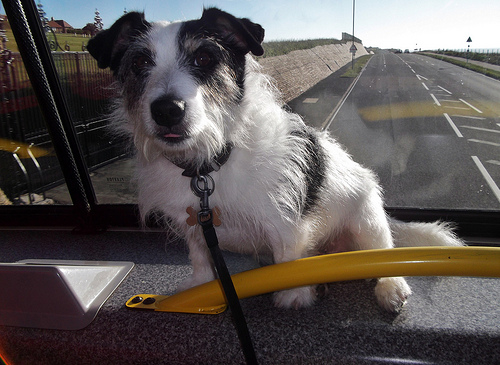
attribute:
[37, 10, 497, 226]
window — large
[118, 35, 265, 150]
dog — black and white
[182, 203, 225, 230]
dog tag — bone shaped